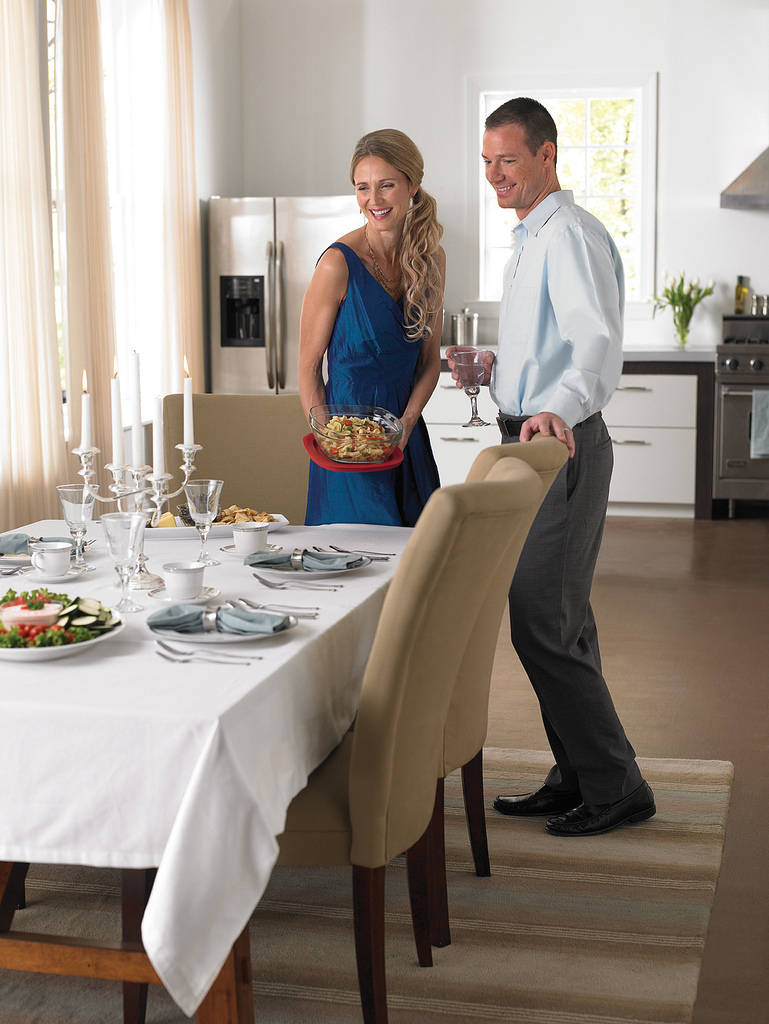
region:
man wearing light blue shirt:
[470, 91, 657, 861]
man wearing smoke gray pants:
[455, 91, 658, 858]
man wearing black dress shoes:
[453, 87, 691, 851]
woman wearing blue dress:
[281, 92, 469, 617]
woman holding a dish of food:
[285, 86, 478, 535]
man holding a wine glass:
[450, 78, 663, 852]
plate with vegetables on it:
[5, 579, 136, 689]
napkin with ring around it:
[132, 585, 295, 646]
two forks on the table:
[149, 628, 259, 680]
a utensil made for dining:
[151, 642, 252, 676]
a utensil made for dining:
[236, 587, 320, 617]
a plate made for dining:
[252, 539, 369, 587]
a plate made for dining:
[153, 594, 292, 648]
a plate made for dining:
[6, 519, 79, 567]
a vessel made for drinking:
[103, 506, 152, 615]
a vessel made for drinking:
[53, 482, 104, 579]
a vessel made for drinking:
[169, 475, 229, 561]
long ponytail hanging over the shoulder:
[397, 177, 442, 342]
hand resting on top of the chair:
[517, 412, 577, 458]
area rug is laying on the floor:
[2, 746, 744, 1022]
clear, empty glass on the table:
[183, 476, 224, 570]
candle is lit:
[175, 356, 204, 446]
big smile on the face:
[361, 207, 397, 221]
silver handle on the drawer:
[611, 379, 654, 399]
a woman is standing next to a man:
[283, 95, 660, 839]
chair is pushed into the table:
[270, 448, 546, 1022]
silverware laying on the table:
[151, 634, 270, 673]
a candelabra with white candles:
[68, 348, 206, 555]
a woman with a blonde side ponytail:
[298, 126, 461, 587]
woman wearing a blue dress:
[295, 126, 465, 532]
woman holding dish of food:
[286, 122, 460, 532]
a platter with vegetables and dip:
[4, 583, 130, 664]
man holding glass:
[433, 89, 663, 833]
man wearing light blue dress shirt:
[443, 89, 668, 847]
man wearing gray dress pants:
[447, 80, 679, 838]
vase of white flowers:
[646, 260, 719, 351]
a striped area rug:
[0, 748, 741, 1016]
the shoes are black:
[504, 740, 676, 866]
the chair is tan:
[335, 437, 508, 866]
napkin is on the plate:
[275, 545, 357, 575]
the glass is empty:
[106, 511, 153, 629]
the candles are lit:
[70, 362, 200, 463]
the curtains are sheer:
[17, 210, 115, 487]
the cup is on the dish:
[159, 561, 209, 608]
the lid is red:
[314, 437, 416, 473]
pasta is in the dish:
[317, 408, 402, 460]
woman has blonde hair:
[310, 113, 463, 363]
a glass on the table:
[174, 474, 231, 575]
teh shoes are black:
[489, 770, 670, 843]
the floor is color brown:
[631, 523, 762, 710]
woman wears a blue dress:
[288, 119, 459, 533]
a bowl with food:
[291, 392, 415, 484]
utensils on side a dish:
[142, 583, 332, 678]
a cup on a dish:
[145, 554, 224, 619]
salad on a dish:
[1, 581, 129, 667]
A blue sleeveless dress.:
[304, 241, 441, 526]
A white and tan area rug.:
[5, 747, 734, 1022]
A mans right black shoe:
[491, 785, 581, 817]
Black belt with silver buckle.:
[493, 410, 605, 436]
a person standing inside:
[317, 188, 435, 479]